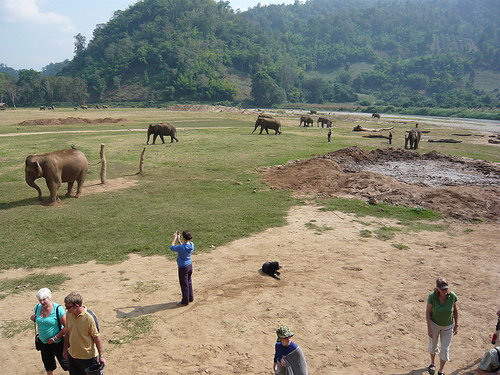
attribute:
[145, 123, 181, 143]
elephant — walking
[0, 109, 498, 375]
field — grassy, grass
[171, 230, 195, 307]
woman — photographer, standing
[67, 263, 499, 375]
ground — grassless, dirt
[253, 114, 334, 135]
elephants — standing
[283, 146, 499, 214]
watering hole — dry, mud, dark brown, muddy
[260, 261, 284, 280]
dog — laying down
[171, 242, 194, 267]
shirt — blue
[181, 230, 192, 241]
hair — up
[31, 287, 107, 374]
people — walking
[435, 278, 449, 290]
visor — brown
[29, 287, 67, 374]
woman — walking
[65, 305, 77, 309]
sunglasses — dark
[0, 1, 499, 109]
trees — dark green, large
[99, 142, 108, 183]
tree stump — wooden, post